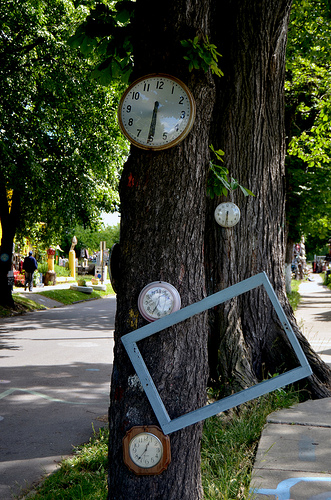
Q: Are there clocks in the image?
A: Yes, there is a clock.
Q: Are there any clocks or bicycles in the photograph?
A: Yes, there is a clock.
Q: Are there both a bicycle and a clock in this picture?
A: No, there is a clock but no bicycles.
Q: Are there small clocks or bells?
A: Yes, there is a small clock.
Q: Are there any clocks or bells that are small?
A: Yes, the clock is small.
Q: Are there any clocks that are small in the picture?
A: Yes, there is a small clock.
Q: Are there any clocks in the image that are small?
A: Yes, there is a clock that is small.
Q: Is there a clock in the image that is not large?
A: Yes, there is a small clock.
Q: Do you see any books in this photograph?
A: No, there are no books.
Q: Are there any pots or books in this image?
A: No, there are no books or pots.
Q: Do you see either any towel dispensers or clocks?
A: Yes, there is a clock.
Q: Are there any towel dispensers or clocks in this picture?
A: Yes, there is a clock.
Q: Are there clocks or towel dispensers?
A: Yes, there is a clock.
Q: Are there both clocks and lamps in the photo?
A: No, there is a clock but no lamps.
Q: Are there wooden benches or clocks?
A: Yes, there is a wood clock.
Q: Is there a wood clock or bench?
A: Yes, there is a wood clock.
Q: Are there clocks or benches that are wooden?
A: Yes, the clock is wooden.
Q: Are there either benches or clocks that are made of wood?
A: Yes, the clock is made of wood.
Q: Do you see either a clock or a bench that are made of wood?
A: Yes, the clock is made of wood.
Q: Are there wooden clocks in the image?
A: Yes, there is a wood clock.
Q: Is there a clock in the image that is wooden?
A: Yes, there is a clock that is wooden.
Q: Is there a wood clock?
A: Yes, there is a clock that is made of wood.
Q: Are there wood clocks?
A: Yes, there is a clock that is made of wood.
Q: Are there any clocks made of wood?
A: Yes, there is a clock that is made of wood.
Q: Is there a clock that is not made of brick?
A: Yes, there is a clock that is made of wood.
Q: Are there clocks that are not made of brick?
A: Yes, there is a clock that is made of wood.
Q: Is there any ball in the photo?
A: No, there are no balls.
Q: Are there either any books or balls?
A: No, there are no balls or books.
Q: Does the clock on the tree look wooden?
A: Yes, the clock is wooden.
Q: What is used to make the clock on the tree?
A: The clock is made of wood.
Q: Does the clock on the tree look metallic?
A: No, the clock is wooden.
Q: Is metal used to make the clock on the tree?
A: No, the clock is made of wood.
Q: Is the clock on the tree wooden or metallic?
A: The clock is wooden.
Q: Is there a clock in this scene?
A: Yes, there is a clock.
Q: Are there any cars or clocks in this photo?
A: Yes, there is a clock.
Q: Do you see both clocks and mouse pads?
A: No, there is a clock but no mouse pads.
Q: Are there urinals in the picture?
A: No, there are no urinals.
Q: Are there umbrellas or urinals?
A: No, there are no urinals or umbrellas.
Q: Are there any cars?
A: No, there are no cars.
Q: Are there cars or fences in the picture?
A: No, there are no cars or fences.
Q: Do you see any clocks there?
A: Yes, there is a clock.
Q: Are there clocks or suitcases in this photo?
A: Yes, there is a clock.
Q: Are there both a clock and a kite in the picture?
A: No, there is a clock but no kites.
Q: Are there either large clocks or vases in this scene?
A: Yes, there is a large clock.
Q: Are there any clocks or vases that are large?
A: Yes, the clock is large.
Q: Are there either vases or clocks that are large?
A: Yes, the clock is large.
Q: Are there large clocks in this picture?
A: Yes, there is a large clock.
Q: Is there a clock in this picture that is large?
A: Yes, there is a large clock.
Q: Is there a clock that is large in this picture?
A: Yes, there is a large clock.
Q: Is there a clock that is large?
A: Yes, there is a clock that is large.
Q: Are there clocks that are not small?
A: Yes, there is a large clock.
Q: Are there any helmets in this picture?
A: No, there are no helmets.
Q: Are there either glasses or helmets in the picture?
A: No, there are no helmets or glasses.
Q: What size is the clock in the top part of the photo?
A: The clock is large.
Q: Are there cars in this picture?
A: No, there are no cars.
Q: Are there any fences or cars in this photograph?
A: No, there are no cars or fences.